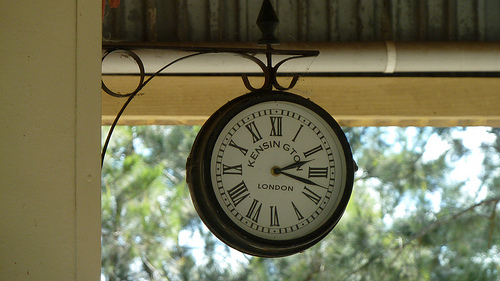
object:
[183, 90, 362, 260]
clock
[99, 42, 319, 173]
display arm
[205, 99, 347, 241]
clock face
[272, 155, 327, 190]
hands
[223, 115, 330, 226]
roman numerals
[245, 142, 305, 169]
kensington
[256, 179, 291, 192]
london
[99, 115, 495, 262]
forrest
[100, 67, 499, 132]
beam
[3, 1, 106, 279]
wall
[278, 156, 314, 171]
clock hand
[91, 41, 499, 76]
pipe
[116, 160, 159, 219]
leaves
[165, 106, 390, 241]
big hand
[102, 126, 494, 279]
leaves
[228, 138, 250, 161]
x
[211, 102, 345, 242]
face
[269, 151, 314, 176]
hand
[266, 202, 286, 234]
vi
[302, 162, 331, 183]
iii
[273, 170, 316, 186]
minute hand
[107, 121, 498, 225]
background